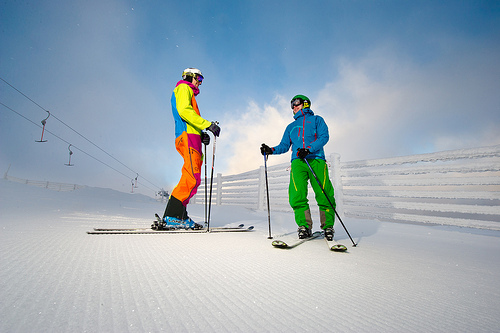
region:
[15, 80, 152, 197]
ski lift with no people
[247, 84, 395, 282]
person with ski poles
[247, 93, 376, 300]
person wearing green pants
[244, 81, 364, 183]
person wearing blue jacket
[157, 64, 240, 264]
person with blue ski boots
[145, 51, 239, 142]
person wearing blue and yellow jacket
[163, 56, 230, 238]
person wearing orange pants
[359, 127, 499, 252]
white snow covering fence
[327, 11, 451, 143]
clouds and blue sky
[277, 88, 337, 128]
green and yellow ski helmet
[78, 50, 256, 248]
skier in bright clothing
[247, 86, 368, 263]
skier in green pants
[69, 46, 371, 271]
two skiers stopped to talk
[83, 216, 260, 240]
extra long pair of skis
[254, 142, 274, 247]
ski pole being used for downhill skiing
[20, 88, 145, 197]
tow ropes on a skiing hill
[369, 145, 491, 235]
snow covered fence on a skiing trail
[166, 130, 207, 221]
bright orange ski pants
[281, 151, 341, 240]
lime green ski pants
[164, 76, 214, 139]
multi-colored ski jacket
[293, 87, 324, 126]
Person wearing green helmet.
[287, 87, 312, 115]
Person wearing goggles on face.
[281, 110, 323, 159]
Person wearing blue jacket.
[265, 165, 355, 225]
Person wearing green pants.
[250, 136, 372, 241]
Person holding ski poles.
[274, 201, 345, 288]
Skis on person's feet.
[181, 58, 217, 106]
Person wearing white helmet.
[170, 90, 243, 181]
Person wearing multi colored snow gear.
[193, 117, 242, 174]
Person wearing dark gloves.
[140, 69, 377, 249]
2 people standing near snow covered fence.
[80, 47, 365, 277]
two people skiing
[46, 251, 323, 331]
ridged groomer marks on the ski slope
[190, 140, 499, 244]
Snow covered fence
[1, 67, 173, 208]
ski tow line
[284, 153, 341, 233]
skier wearing bright green snow pants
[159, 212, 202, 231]
skier wearing bright blue ski boots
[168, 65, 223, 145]
tall man in a multi-colored jacket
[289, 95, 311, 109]
black goggles and a green helmet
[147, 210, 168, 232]
black ski bindings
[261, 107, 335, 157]
blue jacket with a pink zipper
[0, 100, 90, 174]
ski lift up high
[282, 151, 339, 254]
man in green pants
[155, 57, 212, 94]
a man in goggles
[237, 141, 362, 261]
man holding ski poles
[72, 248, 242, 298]
lines in the snow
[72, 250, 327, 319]
sparkles in the snow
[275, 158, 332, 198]
zippers on the man`s pants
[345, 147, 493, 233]
a white snowy fence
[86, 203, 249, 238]
man standing on skiis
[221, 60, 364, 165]
clouds in the sky